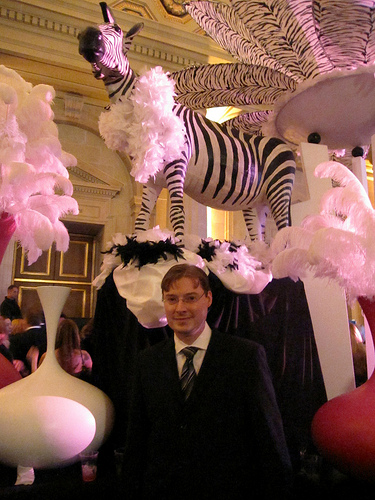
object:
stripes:
[184, 107, 218, 197]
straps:
[80, 349, 85, 366]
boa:
[96, 66, 179, 184]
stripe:
[172, 104, 193, 129]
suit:
[126, 329, 297, 499]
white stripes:
[193, 119, 234, 193]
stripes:
[271, 185, 290, 215]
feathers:
[166, 0, 374, 136]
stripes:
[207, 124, 226, 196]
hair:
[161, 264, 211, 298]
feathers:
[114, 237, 183, 267]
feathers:
[134, 100, 156, 147]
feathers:
[266, 160, 375, 300]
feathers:
[1, 63, 41, 167]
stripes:
[174, 196, 184, 239]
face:
[165, 277, 204, 331]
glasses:
[162, 291, 207, 305]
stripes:
[276, 213, 290, 227]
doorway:
[11, 217, 104, 317]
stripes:
[238, 129, 261, 191]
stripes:
[254, 135, 295, 177]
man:
[126, 263, 301, 500]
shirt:
[173, 320, 212, 379]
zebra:
[78, 1, 296, 247]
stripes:
[263, 154, 294, 189]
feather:
[27, 211, 40, 214]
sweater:
[0, 296, 22, 320]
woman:
[27, 319, 93, 380]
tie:
[179, 347, 198, 401]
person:
[0, 284, 23, 320]